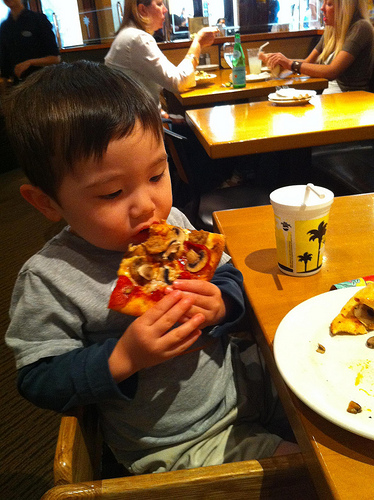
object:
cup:
[269, 182, 333, 278]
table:
[211, 190, 374, 499]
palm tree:
[297, 219, 329, 272]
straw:
[303, 182, 323, 204]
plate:
[272, 285, 373, 441]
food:
[328, 282, 373, 349]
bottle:
[232, 33, 247, 89]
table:
[171, 68, 329, 107]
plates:
[267, 88, 317, 107]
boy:
[2, 60, 302, 476]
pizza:
[107, 218, 228, 324]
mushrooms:
[129, 249, 170, 288]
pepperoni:
[107, 275, 138, 308]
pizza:
[327, 281, 374, 335]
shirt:
[104, 25, 197, 102]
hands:
[123, 278, 226, 371]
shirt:
[3, 206, 246, 473]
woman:
[266, 0, 374, 94]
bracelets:
[290, 60, 302, 75]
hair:
[1, 59, 163, 211]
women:
[102, 0, 220, 109]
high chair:
[39, 414, 307, 500]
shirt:
[314, 18, 374, 94]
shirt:
[0, 7, 60, 82]